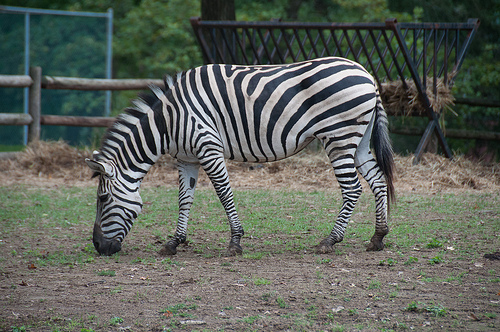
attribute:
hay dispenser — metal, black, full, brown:
[180, 8, 492, 172]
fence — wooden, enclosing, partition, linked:
[1, 64, 221, 162]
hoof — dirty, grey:
[220, 231, 246, 266]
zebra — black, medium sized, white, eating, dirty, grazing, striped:
[58, 53, 422, 279]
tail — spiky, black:
[374, 80, 396, 207]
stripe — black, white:
[210, 63, 249, 166]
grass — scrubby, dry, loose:
[7, 182, 477, 261]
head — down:
[86, 155, 144, 253]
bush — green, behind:
[113, 7, 227, 82]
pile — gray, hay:
[14, 133, 96, 181]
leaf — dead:
[444, 242, 457, 253]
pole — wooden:
[31, 67, 197, 98]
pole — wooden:
[32, 110, 132, 132]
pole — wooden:
[0, 69, 39, 91]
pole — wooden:
[0, 103, 41, 128]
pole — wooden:
[14, 59, 55, 158]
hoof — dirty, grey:
[151, 235, 189, 265]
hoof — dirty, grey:
[306, 230, 341, 258]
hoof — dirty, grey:
[362, 232, 392, 258]